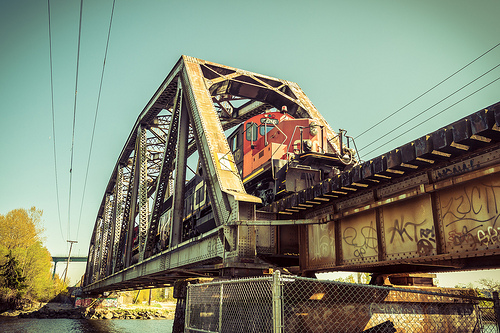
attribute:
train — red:
[102, 110, 352, 268]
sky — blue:
[0, 1, 497, 285]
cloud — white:
[40, 184, 100, 285]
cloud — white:
[19, 121, 103, 212]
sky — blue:
[197, 14, 444, 112]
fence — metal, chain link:
[183, 267, 499, 330]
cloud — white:
[19, 41, 134, 158]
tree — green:
[0, 204, 68, 319]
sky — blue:
[205, 0, 473, 96]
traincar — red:
[231, 115, 351, 193]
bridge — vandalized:
[278, 185, 492, 282]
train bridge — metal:
[64, 55, 493, 331]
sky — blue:
[3, 0, 423, 284]